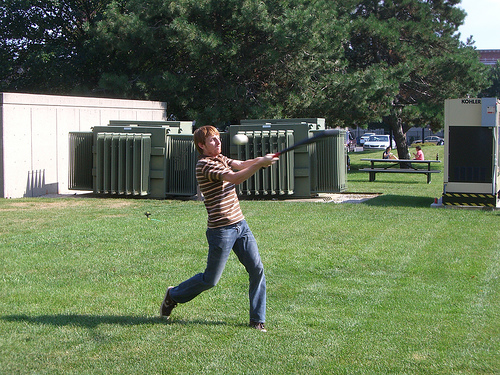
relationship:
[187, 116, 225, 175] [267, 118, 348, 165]
man holding bat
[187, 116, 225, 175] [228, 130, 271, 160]
man missed ball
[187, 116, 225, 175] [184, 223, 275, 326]
man wearing jeans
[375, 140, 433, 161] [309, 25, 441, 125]
kids under tree